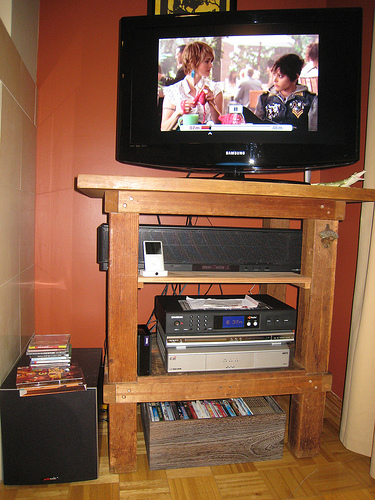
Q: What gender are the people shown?
A: Female.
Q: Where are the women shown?
A: TV.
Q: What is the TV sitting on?
A: Shelf.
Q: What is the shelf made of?
A: Wood.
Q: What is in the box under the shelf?
A: DVD.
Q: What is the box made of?
A: Wood.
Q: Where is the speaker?
A: Shelf below the TV.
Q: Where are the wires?
A: Behind the shelf.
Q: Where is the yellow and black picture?
A: Behind the TV on the wall.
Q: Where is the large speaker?
A: Shelf.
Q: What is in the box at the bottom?
A: Cds.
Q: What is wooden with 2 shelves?
A: Table.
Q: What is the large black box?
A: Speaker.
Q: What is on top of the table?
A: A television.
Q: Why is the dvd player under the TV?
A: To play dvds.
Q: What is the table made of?
A: Wood.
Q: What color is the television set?
A: Black.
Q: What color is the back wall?
A: Rusty brown.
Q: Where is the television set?
A: On a table.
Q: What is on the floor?
A: Boxes.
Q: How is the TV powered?
A: By being plugged in.